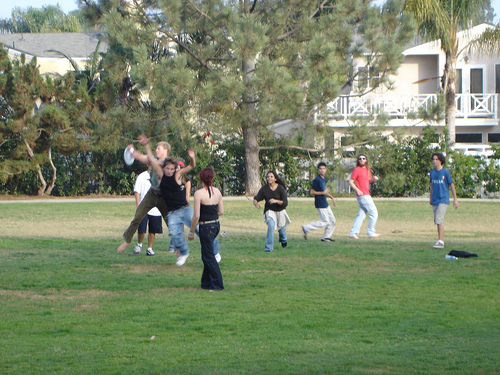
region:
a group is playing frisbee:
[11, 127, 496, 302]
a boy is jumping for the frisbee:
[129, 128, 223, 264]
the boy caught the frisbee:
[120, 140, 171, 250]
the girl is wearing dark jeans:
[194, 221, 222, 298]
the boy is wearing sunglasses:
[352, 151, 373, 181]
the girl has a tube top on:
[190, 187, 225, 228]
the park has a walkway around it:
[0, 182, 498, 208]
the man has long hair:
[353, 150, 372, 181]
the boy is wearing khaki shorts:
[428, 198, 450, 228]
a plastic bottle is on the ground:
[441, 252, 460, 263]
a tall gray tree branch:
[234, 46, 271, 196]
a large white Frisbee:
[120, 142, 134, 164]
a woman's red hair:
[197, 161, 219, 193]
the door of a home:
[471, 66, 483, 111]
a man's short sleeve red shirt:
[351, 160, 373, 197]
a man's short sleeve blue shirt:
[426, 166, 456, 202]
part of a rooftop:
[4, 30, 104, 56]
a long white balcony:
[310, 94, 498, 124]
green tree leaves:
[450, 151, 498, 195]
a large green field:
[1, 202, 498, 373]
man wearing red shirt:
[337, 147, 391, 239]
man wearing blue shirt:
[424, 148, 468, 255]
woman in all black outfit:
[188, 166, 240, 300]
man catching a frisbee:
[118, 133, 171, 265]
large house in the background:
[252, 15, 498, 171]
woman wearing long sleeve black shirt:
[249, 170, 294, 254]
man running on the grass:
[301, 158, 343, 245]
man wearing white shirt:
[130, 163, 172, 260]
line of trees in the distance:
[2, 3, 417, 197]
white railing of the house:
[317, 93, 497, 117]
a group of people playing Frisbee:
[116, 134, 458, 289]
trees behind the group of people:
[0, 1, 499, 196]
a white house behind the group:
[273, 21, 499, 161]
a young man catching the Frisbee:
[116, 140, 183, 252]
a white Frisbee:
[124, 145, 135, 164]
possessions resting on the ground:
[446, 249, 476, 260]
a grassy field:
[0, 194, 499, 374]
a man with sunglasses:
[348, 152, 378, 239]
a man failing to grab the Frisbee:
[137, 128, 222, 266]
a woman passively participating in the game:
[186, 166, 226, 291]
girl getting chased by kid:
[188, 154, 226, 300]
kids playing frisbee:
[125, 119, 185, 227]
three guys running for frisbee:
[261, 150, 396, 244]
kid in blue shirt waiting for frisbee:
[421, 128, 467, 263]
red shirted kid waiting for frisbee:
[348, 152, 380, 240]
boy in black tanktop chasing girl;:
[134, 106, 194, 254]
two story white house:
[330, 22, 498, 94]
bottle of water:
[434, 252, 474, 272]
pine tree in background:
[6, 73, 84, 183]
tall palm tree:
[415, 0, 472, 82]